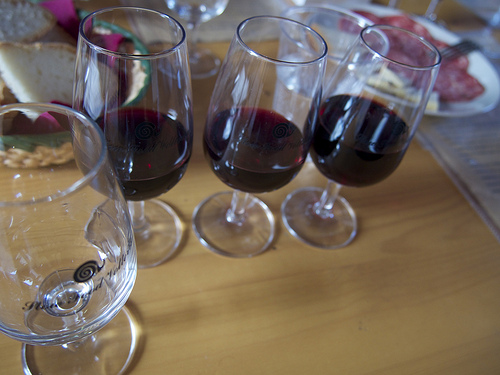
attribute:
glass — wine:
[194, 19, 325, 284]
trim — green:
[0, 10, 155, 150]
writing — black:
[6, 212, 143, 323]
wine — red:
[203, 107, 310, 195]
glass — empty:
[0, 100, 144, 374]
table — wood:
[41, 74, 498, 364]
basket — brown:
[1, 118, 96, 188]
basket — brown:
[1, 96, 88, 177]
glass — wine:
[342, 49, 454, 264]